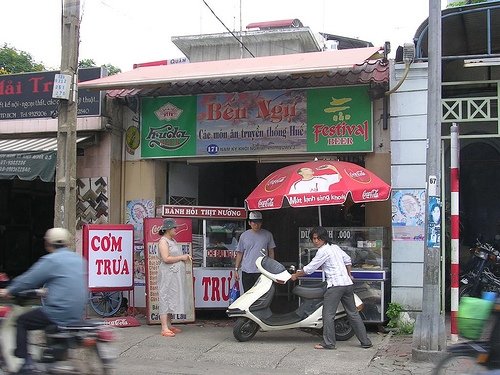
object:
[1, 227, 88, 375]
man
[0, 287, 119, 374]
scooter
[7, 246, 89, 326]
blue shirt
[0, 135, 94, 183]
awning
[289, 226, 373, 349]
man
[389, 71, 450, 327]
ground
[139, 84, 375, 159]
advertisements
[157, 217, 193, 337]
lady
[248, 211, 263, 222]
hat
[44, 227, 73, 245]
hat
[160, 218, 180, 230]
hat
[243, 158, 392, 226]
umbrella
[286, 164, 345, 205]
ads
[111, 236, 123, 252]
letter m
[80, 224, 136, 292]
sign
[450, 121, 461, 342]
pole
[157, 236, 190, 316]
dress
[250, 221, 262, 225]
glasses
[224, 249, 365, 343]
bike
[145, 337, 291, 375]
pavement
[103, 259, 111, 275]
letter r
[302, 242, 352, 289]
shirt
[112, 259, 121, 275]
u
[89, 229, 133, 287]
letter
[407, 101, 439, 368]
keyboard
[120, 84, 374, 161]
sign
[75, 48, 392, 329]
restuarant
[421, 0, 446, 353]
pole